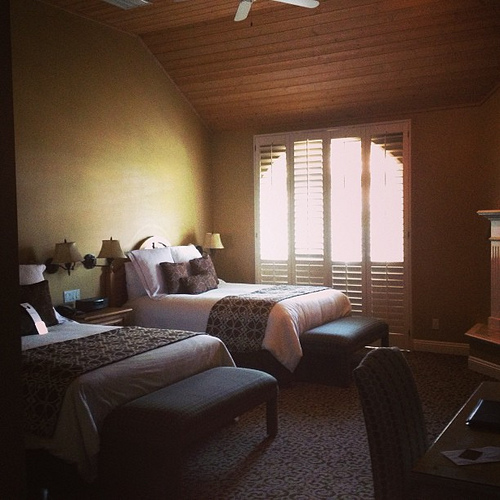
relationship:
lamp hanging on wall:
[45, 238, 85, 276] [11, 0, 215, 310]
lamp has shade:
[45, 238, 85, 276] [53, 242, 87, 266]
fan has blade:
[234, 0, 322, 23] [234, 0, 255, 23]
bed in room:
[104, 234, 353, 374] [8, 0, 499, 499]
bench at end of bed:
[99, 363, 281, 491] [18, 263, 240, 483]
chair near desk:
[351, 346, 431, 500] [411, 380, 500, 500]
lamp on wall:
[82, 236, 128, 271] [11, 0, 215, 310]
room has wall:
[8, 0, 499, 499] [11, 0, 215, 310]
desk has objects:
[411, 380, 500, 500] [441, 397, 500, 468]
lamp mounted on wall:
[82, 236, 128, 271] [11, 0, 215, 310]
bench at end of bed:
[299, 313, 391, 384] [104, 234, 353, 374]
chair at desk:
[351, 346, 431, 500] [411, 380, 500, 500]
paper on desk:
[440, 445, 500, 468] [411, 380, 500, 500]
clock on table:
[76, 296, 112, 313] [55, 303, 133, 328]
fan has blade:
[234, 0, 322, 23] [268, 0, 321, 9]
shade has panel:
[251, 118, 415, 352] [366, 118, 413, 355]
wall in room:
[11, 0, 215, 310] [8, 0, 499, 499]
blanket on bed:
[204, 284, 333, 358] [104, 234, 353, 374]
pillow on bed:
[127, 246, 174, 299] [104, 234, 353, 374]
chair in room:
[351, 346, 431, 500] [8, 0, 499, 499]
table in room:
[55, 303, 133, 328] [8, 0, 499, 499]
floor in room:
[17, 345, 499, 499] [8, 0, 499, 499]